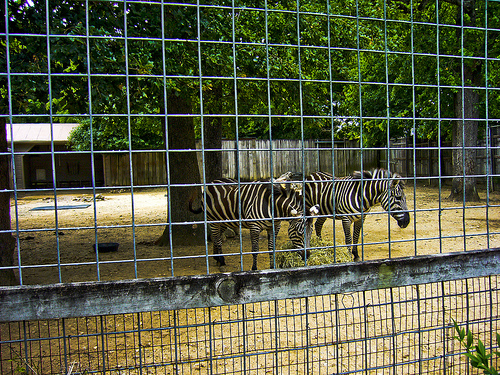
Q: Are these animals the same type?
A: Yes, all the animals are zebras.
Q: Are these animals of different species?
A: No, all the animals are zebras.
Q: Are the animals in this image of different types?
A: No, all the animals are zebras.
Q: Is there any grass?
A: Yes, there is grass.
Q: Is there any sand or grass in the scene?
A: Yes, there is grass.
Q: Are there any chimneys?
A: No, there are no chimneys.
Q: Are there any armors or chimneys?
A: No, there are no chimneys or armors.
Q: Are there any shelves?
A: No, there are no shelves.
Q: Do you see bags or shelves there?
A: No, there are no shelves or bags.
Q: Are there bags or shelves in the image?
A: No, there are no shelves or bags.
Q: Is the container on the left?
A: Yes, the container is on the left of the image.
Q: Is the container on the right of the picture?
A: No, the container is on the left of the image.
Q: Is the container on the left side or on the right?
A: The container is on the left of the image.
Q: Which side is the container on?
A: The container is on the left of the image.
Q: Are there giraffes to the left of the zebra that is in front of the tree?
A: No, there is a container to the left of the zebra.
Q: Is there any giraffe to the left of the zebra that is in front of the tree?
A: No, there is a container to the left of the zebra.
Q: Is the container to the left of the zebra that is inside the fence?
A: Yes, the container is to the left of the zebra.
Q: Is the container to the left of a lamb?
A: No, the container is to the left of the zebra.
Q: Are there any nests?
A: No, there are no nests.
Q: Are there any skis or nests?
A: No, there are no nests or skis.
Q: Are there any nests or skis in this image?
A: No, there are no nests or skis.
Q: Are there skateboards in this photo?
A: No, there are no skateboards.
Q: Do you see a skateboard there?
A: No, there are no skateboards.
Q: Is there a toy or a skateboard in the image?
A: No, there are no skateboards or toys.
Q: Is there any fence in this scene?
A: Yes, there is a fence.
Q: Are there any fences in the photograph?
A: Yes, there is a fence.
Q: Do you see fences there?
A: Yes, there is a fence.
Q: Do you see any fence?
A: Yes, there is a fence.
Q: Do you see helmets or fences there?
A: Yes, there is a fence.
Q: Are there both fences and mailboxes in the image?
A: No, there is a fence but no mailboxes.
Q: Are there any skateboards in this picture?
A: No, there are no skateboards.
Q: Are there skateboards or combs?
A: No, there are no skateboards or combs.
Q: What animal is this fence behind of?
A: The fence is behind the zebra.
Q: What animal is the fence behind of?
A: The fence is behind the zebra.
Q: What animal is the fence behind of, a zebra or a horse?
A: The fence is behind a zebra.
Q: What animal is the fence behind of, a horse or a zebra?
A: The fence is behind a zebra.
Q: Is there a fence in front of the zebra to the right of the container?
A: No, the fence is behind the zebra.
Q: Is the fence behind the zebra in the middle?
A: Yes, the fence is behind the zebra.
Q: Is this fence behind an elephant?
A: No, the fence is behind the zebra.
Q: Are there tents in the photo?
A: No, there are no tents.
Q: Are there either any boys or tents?
A: No, there are no tents or boys.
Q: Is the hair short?
A: Yes, the hair is short.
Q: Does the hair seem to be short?
A: Yes, the hair is short.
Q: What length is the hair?
A: The hair is short.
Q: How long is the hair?
A: The hair is short.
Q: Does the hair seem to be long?
A: No, the hair is short.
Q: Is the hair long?
A: No, the hair is short.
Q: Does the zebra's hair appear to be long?
A: No, the hair is short.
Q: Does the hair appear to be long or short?
A: The hair is short.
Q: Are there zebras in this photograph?
A: Yes, there is a zebra.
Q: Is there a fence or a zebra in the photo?
A: Yes, there is a zebra.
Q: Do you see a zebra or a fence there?
A: Yes, there is a zebra.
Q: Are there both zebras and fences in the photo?
A: Yes, there are both a zebra and a fence.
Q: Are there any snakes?
A: No, there are no snakes.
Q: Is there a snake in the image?
A: No, there are no snakes.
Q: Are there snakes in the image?
A: No, there are no snakes.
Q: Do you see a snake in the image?
A: No, there are no snakes.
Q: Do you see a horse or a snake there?
A: No, there are no snakes or horses.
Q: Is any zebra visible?
A: Yes, there is a zebra.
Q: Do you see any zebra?
A: Yes, there is a zebra.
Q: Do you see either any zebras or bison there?
A: Yes, there is a zebra.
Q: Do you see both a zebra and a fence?
A: Yes, there are both a zebra and a fence.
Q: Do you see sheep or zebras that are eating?
A: Yes, the zebra is eating.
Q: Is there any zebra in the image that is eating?
A: Yes, there is a zebra that is eating.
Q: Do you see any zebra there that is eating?
A: Yes, there is a zebra that is eating.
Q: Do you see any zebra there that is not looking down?
A: Yes, there is a zebra that is eating .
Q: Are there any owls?
A: No, there are no owls.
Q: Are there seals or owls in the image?
A: No, there are no owls or seals.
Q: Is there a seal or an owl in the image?
A: No, there are no owls or seals.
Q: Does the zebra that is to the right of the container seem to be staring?
A: No, the zebra is eating.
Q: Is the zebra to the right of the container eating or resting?
A: The zebra is eating.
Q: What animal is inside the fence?
A: The zebra is inside the fence.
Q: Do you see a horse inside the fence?
A: No, there is a zebra inside the fence.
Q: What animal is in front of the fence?
A: The zebra is in front of the fence.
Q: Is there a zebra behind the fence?
A: No, the zebra is in front of the fence.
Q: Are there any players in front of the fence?
A: No, there is a zebra in front of the fence.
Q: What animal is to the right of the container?
A: The animal is a zebra.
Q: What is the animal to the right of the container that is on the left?
A: The animal is a zebra.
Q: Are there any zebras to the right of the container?
A: Yes, there is a zebra to the right of the container.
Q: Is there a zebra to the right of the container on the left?
A: Yes, there is a zebra to the right of the container.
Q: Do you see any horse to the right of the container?
A: No, there is a zebra to the right of the container.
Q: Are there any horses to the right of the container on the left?
A: No, there is a zebra to the right of the container.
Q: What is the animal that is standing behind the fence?
A: The animal is a zebra.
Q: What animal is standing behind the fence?
A: The animal is a zebra.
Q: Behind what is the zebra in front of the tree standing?
A: The zebra is standing behind the fence.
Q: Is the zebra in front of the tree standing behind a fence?
A: Yes, the zebra is standing behind a fence.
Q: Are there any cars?
A: No, there are no cars.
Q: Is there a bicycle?
A: No, there are no bicycles.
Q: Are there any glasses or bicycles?
A: No, there are no bicycles or glasses.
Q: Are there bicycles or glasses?
A: No, there are no bicycles or glasses.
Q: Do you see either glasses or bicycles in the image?
A: No, there are no bicycles or glasses.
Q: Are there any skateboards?
A: No, there are no skateboards.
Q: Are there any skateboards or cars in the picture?
A: No, there are no skateboards or cars.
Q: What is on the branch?
A: The leaves are on the branch.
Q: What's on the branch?
A: The leaves are on the branch.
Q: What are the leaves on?
A: The leaves are on the branch.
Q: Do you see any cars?
A: No, there are no cars.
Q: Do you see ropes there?
A: No, there are no ropes.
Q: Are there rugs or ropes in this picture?
A: No, there are no ropes or rugs.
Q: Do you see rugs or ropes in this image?
A: No, there are no ropes or rugs.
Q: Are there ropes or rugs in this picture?
A: No, there are no ropes or rugs.